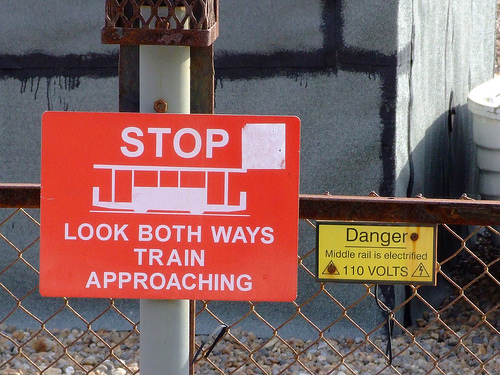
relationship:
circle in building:
[443, 84, 464, 133] [3, 4, 498, 326]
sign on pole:
[37, 109, 297, 299] [139, 45, 189, 373]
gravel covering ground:
[2, 261, 495, 373] [3, 216, 498, 373]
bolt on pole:
[398, 229, 430, 247] [112, 69, 217, 375]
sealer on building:
[3, 5, 427, 319] [0, 0, 499, 339]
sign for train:
[39, 112, 298, 300] [132, 186, 207, 214]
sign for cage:
[316, 220, 437, 285] [0, 183, 498, 375]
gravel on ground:
[0, 334, 496, 373] [338, 338, 438, 373]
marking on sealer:
[341, 258, 408, 293] [0, 0, 398, 339]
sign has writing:
[37, 109, 297, 299] [76, 269, 251, 309]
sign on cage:
[315, 218, 437, 285] [0, 183, 498, 375]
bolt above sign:
[153, 93, 167, 115] [37, 109, 297, 299]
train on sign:
[128, 184, 207, 221] [37, 109, 297, 299]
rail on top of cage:
[303, 193, 499, 228] [0, 183, 498, 375]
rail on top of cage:
[1, 179, 42, 211] [0, 183, 498, 375]